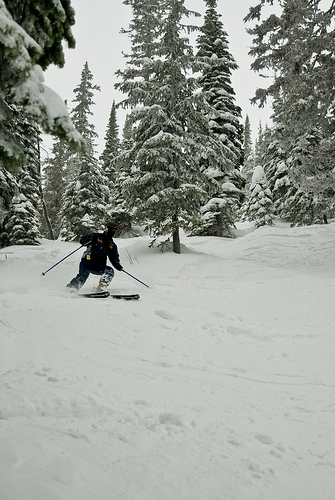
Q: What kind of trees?
A: Pine.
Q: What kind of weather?
A: Overcast.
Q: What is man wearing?
A: Jacket.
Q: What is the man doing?
A: Skiing.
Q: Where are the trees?
A: Ground.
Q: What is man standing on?
A: Skis.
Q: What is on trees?
A: Snow.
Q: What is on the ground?
A: Snow.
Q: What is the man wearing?
A: Jacket.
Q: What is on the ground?
A: Snow.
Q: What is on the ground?
A: Skier.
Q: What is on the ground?
A: Snow.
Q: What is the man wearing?
A: Mask.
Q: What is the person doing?
A: Skiing.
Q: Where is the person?
A: Ski slope.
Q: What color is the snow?
A: White.